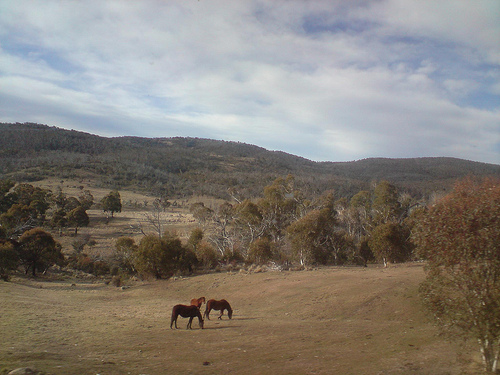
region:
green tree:
[101, 186, 128, 239]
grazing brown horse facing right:
[203, 284, 251, 327]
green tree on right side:
[371, 209, 432, 273]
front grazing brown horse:
[160, 294, 215, 342]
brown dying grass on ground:
[297, 327, 384, 370]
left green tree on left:
[23, 230, 70, 273]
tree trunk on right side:
[469, 325, 496, 372]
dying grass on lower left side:
[6, 322, 71, 371]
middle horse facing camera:
[187, 292, 212, 314]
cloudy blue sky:
[211, 21, 382, 146]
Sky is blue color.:
[14, 28, 66, 77]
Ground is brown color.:
[263, 287, 338, 351]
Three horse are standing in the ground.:
[166, 295, 238, 335]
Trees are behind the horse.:
[33, 207, 433, 264]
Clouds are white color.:
[159, 33, 284, 106]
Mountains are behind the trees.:
[14, 113, 499, 198]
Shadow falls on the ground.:
[158, 300, 260, 341]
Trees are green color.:
[8, 192, 56, 261]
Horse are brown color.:
[158, 288, 238, 336]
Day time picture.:
[18, 32, 465, 364]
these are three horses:
[168, 293, 235, 330]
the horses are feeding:
[166, 290, 238, 330]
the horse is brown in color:
[213, 298, 223, 308]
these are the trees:
[259, 190, 384, 267]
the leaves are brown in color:
[289, 200, 344, 238]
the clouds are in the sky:
[201, 15, 274, 92]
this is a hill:
[136, 132, 183, 182]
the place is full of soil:
[61, 290, 107, 346]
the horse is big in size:
[169, 302, 203, 326]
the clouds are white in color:
[175, 35, 245, 89]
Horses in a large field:
[26, 180, 458, 370]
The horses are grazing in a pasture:
[83, 277, 320, 370]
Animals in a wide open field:
[55, 102, 471, 357]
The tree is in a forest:
[95, 185, 120, 220]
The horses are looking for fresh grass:
[146, 275, 246, 346]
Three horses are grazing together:
[145, 280, 260, 345]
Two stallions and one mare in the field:
[140, 275, 280, 350]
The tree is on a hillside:
[420, 176, 495, 368]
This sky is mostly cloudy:
[375, 22, 495, 122]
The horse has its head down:
[203, 296, 237, 326]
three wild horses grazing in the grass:
[167, 296, 233, 328]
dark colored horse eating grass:
[169, 306, 204, 331]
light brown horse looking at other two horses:
[189, 298, 206, 310]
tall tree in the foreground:
[421, 176, 498, 371]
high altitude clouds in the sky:
[0, 1, 498, 165]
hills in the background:
[0, 121, 496, 199]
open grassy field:
[0, 280, 455, 370]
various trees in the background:
[1, 179, 420, 281]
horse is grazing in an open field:
[207, 297, 232, 321]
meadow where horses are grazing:
[0, 264, 423, 373]